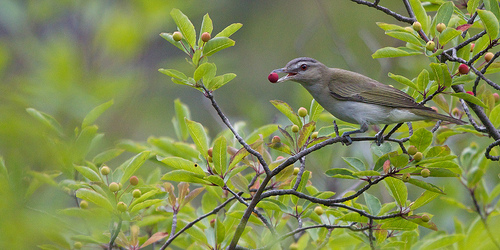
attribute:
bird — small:
[269, 57, 468, 147]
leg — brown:
[345, 127, 370, 136]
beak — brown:
[270, 67, 292, 83]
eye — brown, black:
[299, 63, 309, 71]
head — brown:
[269, 56, 330, 88]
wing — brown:
[326, 78, 435, 112]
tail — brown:
[403, 108, 469, 126]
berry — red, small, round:
[267, 71, 279, 83]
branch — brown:
[229, 135, 400, 249]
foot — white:
[337, 132, 353, 146]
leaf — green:
[369, 45, 424, 59]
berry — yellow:
[170, 30, 184, 42]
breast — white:
[312, 91, 349, 123]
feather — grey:
[328, 80, 362, 98]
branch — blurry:
[470, 188, 500, 248]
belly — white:
[329, 100, 391, 126]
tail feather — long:
[409, 109, 470, 127]